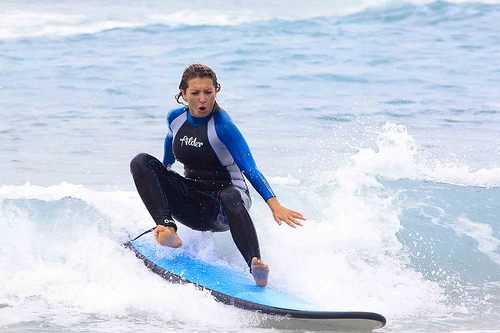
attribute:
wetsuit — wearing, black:
[128, 104, 278, 273]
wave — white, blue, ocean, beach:
[3, 115, 498, 333]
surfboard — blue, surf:
[118, 234, 387, 332]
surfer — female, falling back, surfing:
[129, 64, 306, 293]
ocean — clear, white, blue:
[0, 2, 500, 333]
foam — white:
[428, 201, 500, 280]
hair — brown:
[173, 63, 222, 113]